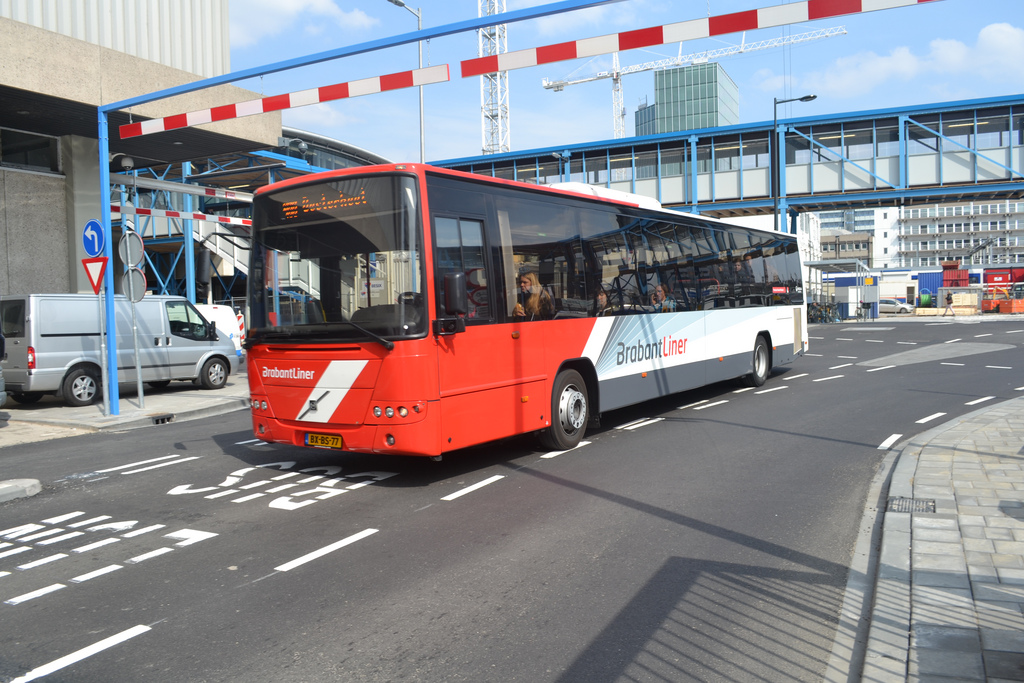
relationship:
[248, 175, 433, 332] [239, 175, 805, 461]
windshield on bus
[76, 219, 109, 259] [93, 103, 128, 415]
sign on pole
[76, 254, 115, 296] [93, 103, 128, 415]
sign on pole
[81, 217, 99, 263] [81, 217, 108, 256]
arrow on sign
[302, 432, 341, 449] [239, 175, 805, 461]
plate on bus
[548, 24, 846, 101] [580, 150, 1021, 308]
crane next to building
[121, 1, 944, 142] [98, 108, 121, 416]
stripedboards hanging from pole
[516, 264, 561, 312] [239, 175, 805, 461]
woman riding inside bus